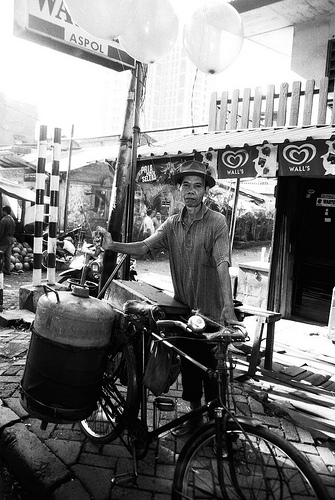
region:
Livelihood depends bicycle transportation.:
[70, 154, 281, 485]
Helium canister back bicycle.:
[22, 208, 126, 436]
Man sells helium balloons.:
[67, 5, 237, 346]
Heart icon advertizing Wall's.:
[219, 131, 332, 179]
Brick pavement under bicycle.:
[98, 391, 332, 495]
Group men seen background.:
[131, 198, 170, 255]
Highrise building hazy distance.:
[140, 28, 211, 139]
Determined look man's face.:
[164, 161, 219, 223]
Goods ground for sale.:
[0, 192, 34, 283]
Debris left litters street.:
[247, 304, 334, 409]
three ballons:
[85, 2, 255, 83]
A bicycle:
[128, 328, 224, 473]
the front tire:
[173, 429, 313, 499]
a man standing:
[170, 165, 240, 332]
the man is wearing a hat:
[175, 159, 216, 179]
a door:
[296, 213, 329, 298]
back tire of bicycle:
[98, 378, 139, 429]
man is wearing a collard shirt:
[169, 203, 222, 297]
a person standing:
[0, 206, 18, 275]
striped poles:
[32, 171, 57, 285]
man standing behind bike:
[82, 146, 283, 453]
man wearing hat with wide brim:
[78, 150, 273, 458]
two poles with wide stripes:
[28, 117, 66, 275]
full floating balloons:
[55, 0, 252, 94]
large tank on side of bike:
[15, 261, 122, 428]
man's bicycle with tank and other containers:
[58, 268, 322, 493]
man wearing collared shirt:
[86, 151, 255, 445]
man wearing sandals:
[86, 152, 246, 443]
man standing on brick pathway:
[91, 152, 256, 453]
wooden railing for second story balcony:
[203, 74, 333, 137]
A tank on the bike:
[10, 274, 111, 427]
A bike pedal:
[97, 436, 148, 489]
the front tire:
[175, 413, 333, 499]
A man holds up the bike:
[89, 153, 264, 379]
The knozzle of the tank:
[87, 226, 110, 259]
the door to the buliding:
[291, 205, 334, 330]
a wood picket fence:
[211, 76, 333, 126]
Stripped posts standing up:
[35, 123, 62, 287]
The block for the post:
[19, 276, 66, 309]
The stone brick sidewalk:
[11, 440, 111, 497]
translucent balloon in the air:
[175, 0, 254, 100]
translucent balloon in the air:
[113, 0, 181, 71]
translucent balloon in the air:
[59, 0, 134, 48]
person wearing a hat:
[91, 154, 254, 458]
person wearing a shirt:
[89, 152, 256, 407]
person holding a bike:
[67, 155, 326, 499]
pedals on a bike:
[97, 389, 184, 493]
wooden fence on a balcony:
[200, 72, 334, 135]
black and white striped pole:
[21, 116, 51, 306]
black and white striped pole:
[40, 123, 66, 300]